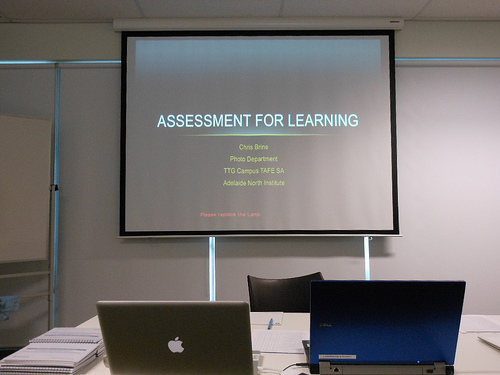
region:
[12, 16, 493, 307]
screen with black border against white wall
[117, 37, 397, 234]
screen showing information in different colors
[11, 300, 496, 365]
white surface with laptops and books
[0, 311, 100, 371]
spiral-bound notebooks on edge of table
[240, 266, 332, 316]
curve on top of black chair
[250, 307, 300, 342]
blue pen over paper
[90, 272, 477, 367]
covers lifted over laptops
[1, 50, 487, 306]
metal rods against wall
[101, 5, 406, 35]
container for screen under ceiling tiles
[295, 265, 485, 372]
THE LAPTOP IS BLUE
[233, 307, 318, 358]
THE PAPERS ARE ON THE DESK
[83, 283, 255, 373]
THE LAPTOP IS GREY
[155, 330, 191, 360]
THE APPLE IS ON THE LAPTOP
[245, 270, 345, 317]
THE CHAIR IS BLACK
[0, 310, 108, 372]
THE BOOKS ARE ON THE DESK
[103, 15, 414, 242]
THE SCREEN IS DOWN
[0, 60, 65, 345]
THE DOOR IS OPEN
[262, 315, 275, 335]
THE PEN IS BLUE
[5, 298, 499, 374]
THE DESK IS BIG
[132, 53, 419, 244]
a big screen in wall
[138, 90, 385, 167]
a text in the screen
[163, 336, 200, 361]
logo in the laptop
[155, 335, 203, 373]
apple brand of laptop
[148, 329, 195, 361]
apple design in laptop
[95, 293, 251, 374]
a laptop on the table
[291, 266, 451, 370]
another laptop on table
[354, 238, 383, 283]
a part of stand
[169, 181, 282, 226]
red text in the screen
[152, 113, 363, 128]
these are words on the screen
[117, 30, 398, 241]
this is a projector screen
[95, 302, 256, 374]
this a apple computer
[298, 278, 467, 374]
thats a laptop computer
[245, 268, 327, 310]
this is a black chair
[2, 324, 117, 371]
this is a book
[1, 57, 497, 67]
this is a rail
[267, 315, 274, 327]
thats a blue pen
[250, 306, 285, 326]
thats some white paper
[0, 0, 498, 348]
thats a white wall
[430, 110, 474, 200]
this is the wall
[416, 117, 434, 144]
the wall is white in color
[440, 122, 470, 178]
the wall is clean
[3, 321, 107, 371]
this is a book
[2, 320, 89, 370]
the book is open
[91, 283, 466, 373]
these are two laptops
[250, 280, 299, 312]
this is a chair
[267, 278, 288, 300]
the chair is blac in color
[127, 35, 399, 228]
this is a screen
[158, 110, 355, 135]
the writings are in bold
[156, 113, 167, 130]
white print style letter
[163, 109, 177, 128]
white print style letter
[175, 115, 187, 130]
white print style letter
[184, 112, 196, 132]
white print style letter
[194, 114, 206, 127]
white print style letter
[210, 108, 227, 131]
white print style letter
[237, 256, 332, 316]
The top of a black chair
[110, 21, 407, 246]
A big projector screen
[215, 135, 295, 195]
Words written in yellow letters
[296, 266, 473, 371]
The back of a black laptop computer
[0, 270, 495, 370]
Two laptops sitting on the table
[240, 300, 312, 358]
White papers on the table